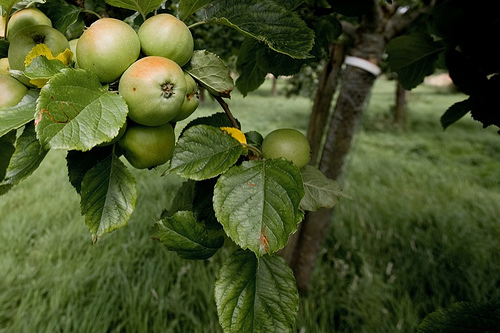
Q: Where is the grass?
A: Under the tree.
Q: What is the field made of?
A: Grass.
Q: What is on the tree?
A: Apples.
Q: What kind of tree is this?
A: An apple tree.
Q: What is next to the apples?
A: Green leaves.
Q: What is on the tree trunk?
A: Bark.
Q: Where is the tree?
A: In the grassy field.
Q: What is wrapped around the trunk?
A: A white tie.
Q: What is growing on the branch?
A: Apples.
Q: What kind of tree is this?
A: Apple tree.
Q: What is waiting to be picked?
A: Apples.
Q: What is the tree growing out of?
A: The ground.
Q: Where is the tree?
A: In an orchard.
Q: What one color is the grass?
A: Green.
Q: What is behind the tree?
A: More trees.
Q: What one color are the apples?
A: Green.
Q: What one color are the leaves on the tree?
A: Green.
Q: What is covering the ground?
A: Grass.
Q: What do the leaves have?
A: Veins.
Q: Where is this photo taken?
A: In a field.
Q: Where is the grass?
A: Bottom of picture.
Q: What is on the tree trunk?
A: White stripe.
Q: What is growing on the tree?
A: Fruit.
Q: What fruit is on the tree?
A: Apple.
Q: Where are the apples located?
A: On the tree.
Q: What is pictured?
A: Apples.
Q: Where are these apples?
A: On a tree.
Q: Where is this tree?
A: An orchard.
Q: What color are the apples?
A: Green.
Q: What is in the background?
A: An orchard.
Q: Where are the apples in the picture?
A: The foreground.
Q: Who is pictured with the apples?
A: No one.